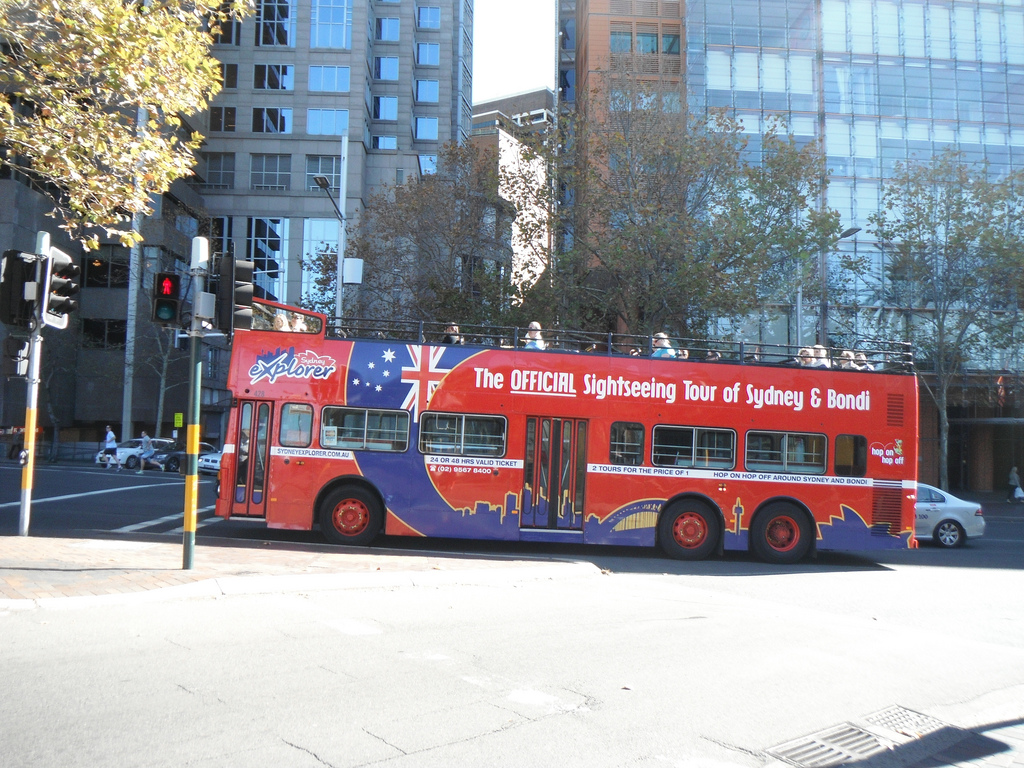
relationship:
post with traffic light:
[185, 351, 203, 580] [138, 256, 199, 326]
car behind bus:
[916, 485, 975, 540] [218, 318, 944, 547]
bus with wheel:
[220, 323, 918, 566] [751, 491, 814, 565]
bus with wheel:
[220, 323, 918, 566] [659, 489, 718, 569]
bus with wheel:
[220, 323, 918, 566] [307, 467, 392, 539]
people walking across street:
[105, 422, 158, 468] [30, 446, 216, 539]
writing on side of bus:
[464, 366, 879, 406] [220, 323, 918, 566]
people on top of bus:
[442, 314, 888, 369] [237, 333, 938, 558]